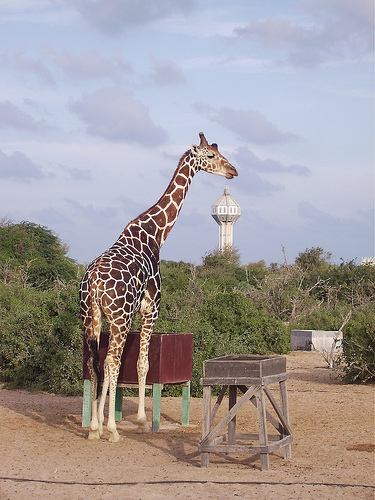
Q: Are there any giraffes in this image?
A: Yes, there is a giraffe.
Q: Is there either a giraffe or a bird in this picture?
A: Yes, there is a giraffe.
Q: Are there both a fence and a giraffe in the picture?
A: No, there is a giraffe but no fences.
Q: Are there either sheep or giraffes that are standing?
A: Yes, the giraffe is standing.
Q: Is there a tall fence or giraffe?
A: Yes, there is a tall giraffe.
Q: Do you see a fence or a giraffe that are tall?
A: Yes, the giraffe is tall.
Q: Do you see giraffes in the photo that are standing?
A: Yes, there is a giraffe that is standing.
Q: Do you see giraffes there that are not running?
A: Yes, there is a giraffe that is standing .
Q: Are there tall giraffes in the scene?
A: Yes, there is a tall giraffe.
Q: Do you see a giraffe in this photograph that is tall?
A: Yes, there is a tall giraffe.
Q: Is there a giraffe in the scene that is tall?
A: Yes, there is a giraffe that is tall.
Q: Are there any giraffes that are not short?
A: Yes, there is a tall giraffe.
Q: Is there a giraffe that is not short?
A: Yes, there is a tall giraffe.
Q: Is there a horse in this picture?
A: No, there are no horses.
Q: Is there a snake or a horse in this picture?
A: No, there are no horses or snakes.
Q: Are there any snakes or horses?
A: No, there are no horses or snakes.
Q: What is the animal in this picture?
A: The animal is a giraffe.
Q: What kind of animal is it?
A: The animal is a giraffe.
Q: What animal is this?
A: This is a giraffe.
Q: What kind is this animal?
A: This is a giraffe.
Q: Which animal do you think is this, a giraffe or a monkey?
A: This is a giraffe.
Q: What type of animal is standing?
A: The animal is a giraffe.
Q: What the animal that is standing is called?
A: The animal is a giraffe.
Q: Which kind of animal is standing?
A: The animal is a giraffe.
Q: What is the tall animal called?
A: The animal is a giraffe.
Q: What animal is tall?
A: The animal is a giraffe.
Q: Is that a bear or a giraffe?
A: That is a giraffe.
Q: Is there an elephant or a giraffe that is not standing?
A: No, there is a giraffe but it is standing.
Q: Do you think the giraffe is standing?
A: Yes, the giraffe is standing.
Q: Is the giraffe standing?
A: Yes, the giraffe is standing.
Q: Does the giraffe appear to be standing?
A: Yes, the giraffe is standing.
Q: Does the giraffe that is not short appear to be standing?
A: Yes, the giraffe is standing.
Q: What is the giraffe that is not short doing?
A: The giraffe is standing.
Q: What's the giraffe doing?
A: The giraffe is standing.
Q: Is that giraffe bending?
A: No, the giraffe is standing.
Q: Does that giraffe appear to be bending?
A: No, the giraffe is standing.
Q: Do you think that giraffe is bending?
A: No, the giraffe is standing.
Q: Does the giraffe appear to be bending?
A: No, the giraffe is standing.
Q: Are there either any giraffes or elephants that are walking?
A: No, there is a giraffe but it is standing.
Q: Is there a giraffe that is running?
A: No, there is a giraffe but it is standing.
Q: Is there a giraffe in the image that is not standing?
A: No, there is a giraffe but it is standing.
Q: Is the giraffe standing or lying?
A: The giraffe is standing.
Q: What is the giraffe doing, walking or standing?
A: The giraffe is standing.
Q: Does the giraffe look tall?
A: Yes, the giraffe is tall.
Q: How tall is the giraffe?
A: The giraffe is tall.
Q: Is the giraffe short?
A: No, the giraffe is tall.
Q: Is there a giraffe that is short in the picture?
A: No, there is a giraffe but it is tall.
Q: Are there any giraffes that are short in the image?
A: No, there is a giraffe but it is tall.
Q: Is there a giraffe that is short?
A: No, there is a giraffe but it is tall.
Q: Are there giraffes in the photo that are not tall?
A: No, there is a giraffe but it is tall.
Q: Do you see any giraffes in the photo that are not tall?
A: No, there is a giraffe but it is tall.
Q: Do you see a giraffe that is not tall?
A: No, there is a giraffe but it is tall.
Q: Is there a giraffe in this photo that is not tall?
A: No, there is a giraffe but it is tall.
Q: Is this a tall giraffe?
A: Yes, this is a tall giraffe.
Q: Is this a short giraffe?
A: No, this is a tall giraffe.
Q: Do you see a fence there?
A: No, there are no fences.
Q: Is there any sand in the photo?
A: Yes, there is sand.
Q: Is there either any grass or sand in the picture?
A: Yes, there is sand.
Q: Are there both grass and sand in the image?
A: No, there is sand but no grass.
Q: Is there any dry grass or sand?
A: Yes, there is dry sand.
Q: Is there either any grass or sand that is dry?
A: Yes, the sand is dry.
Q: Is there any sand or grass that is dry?
A: Yes, the sand is dry.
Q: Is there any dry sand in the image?
A: Yes, there is dry sand.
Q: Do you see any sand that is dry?
A: Yes, there is sand that is dry.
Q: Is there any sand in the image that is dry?
A: Yes, there is sand that is dry.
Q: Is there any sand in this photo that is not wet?
A: Yes, there is dry sand.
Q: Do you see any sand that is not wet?
A: Yes, there is dry sand.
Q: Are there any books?
A: No, there are no books.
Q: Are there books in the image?
A: No, there are no books.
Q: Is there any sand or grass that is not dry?
A: No, there is sand but it is dry.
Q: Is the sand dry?
A: Yes, the sand is dry.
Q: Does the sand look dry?
A: Yes, the sand is dry.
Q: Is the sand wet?
A: No, the sand is dry.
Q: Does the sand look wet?
A: No, the sand is dry.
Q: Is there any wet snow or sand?
A: No, there is sand but it is dry.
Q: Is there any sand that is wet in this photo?
A: No, there is sand but it is dry.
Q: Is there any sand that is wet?
A: No, there is sand but it is dry.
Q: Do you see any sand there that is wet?
A: No, there is sand but it is dry.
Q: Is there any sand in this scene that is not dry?
A: No, there is sand but it is dry.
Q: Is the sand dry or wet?
A: The sand is dry.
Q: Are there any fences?
A: No, there are no fences.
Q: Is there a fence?
A: No, there are no fences.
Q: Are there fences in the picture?
A: No, there are no fences.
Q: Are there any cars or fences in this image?
A: No, there are no fences or cars.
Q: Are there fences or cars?
A: No, there are no fences or cars.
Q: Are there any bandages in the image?
A: No, there are no bandages.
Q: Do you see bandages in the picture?
A: No, there are no bandages.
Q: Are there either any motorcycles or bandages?
A: No, there are no bandages or motorcycles.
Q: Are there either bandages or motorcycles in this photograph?
A: No, there are no bandages or motorcycles.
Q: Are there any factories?
A: No, there are no factories.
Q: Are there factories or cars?
A: No, there are no factories or cars.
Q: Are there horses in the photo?
A: No, there are no horses.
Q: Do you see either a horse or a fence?
A: No, there are no horses or fences.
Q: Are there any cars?
A: No, there are no cars.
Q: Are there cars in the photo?
A: No, there are no cars.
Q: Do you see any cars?
A: No, there are no cars.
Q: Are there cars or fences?
A: No, there are no cars or fences.